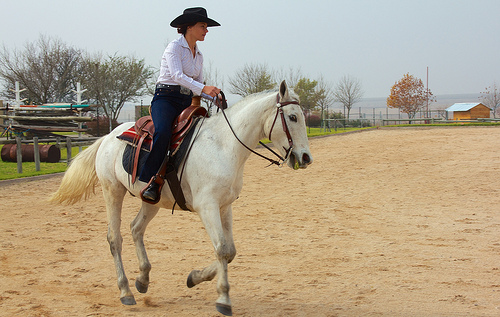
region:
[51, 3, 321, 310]
a lady riding a white horse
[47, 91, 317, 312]
a white horse a person is riding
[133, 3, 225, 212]
a woman on the white horse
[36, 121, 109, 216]
a wagging tail of the white horse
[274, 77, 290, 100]
an ear of the white horse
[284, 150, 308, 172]
a bit on the horse mouth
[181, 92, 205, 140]
a saddle on the horse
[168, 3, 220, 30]
a hat the woman is wearing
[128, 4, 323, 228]
a woman in jeans riding a horse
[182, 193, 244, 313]
two front legs of the horse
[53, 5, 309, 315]
A woman riding a white horse.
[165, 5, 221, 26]
A black cowboy hat on the woman's head.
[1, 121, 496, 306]
There is a dirt field.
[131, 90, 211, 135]
A brown saddle on the horse's back.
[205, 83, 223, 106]
The woman is holding the reins.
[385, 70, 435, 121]
A tree with orange leaves in the distance.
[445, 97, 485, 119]
There is a small brown structure near the field.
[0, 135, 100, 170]
A wooden fence behind the horse.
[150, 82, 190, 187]
The woman is wearing blue pants.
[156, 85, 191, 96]
There is a black belt with a silver buckle.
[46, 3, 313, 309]
rider on moving white horse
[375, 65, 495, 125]
tree and low building at end of dirt field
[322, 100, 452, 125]
wooden and metal fencing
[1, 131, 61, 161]
rusty cylinder on ground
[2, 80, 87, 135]
wooden poles in front of white supports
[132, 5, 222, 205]
black hat with wide brim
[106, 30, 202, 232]
white shirt with dark jeans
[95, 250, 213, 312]
horse's legs above ground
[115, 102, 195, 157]
striped blanket under brown saddle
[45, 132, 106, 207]
blonde tail flowing behind horse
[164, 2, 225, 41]
woman wearing black hat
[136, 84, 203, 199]
woman wearing dark blue jeans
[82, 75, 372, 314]
woman riding white horse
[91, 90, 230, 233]
brown leather saddle on a blanket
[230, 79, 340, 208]
horse is wearing reins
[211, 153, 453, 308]
sand on the ground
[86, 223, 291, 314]
horse is trotting around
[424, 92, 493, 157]
yellow house in the distance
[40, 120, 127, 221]
pony has yellow tail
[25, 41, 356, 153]
trees have no leaves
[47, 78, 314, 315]
a pretty white horse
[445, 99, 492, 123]
a small wooden building with a tin roof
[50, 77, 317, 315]
a white hirse galloping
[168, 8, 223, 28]
a woman's black cowgirl hat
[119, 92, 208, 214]
a brown leather saddle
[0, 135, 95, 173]
a section of wooden fence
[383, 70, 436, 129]
a tree with fall leafs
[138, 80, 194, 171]
a dark pair of blue jean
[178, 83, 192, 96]
a big silver buckle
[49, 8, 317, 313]
a woman riding a white horse